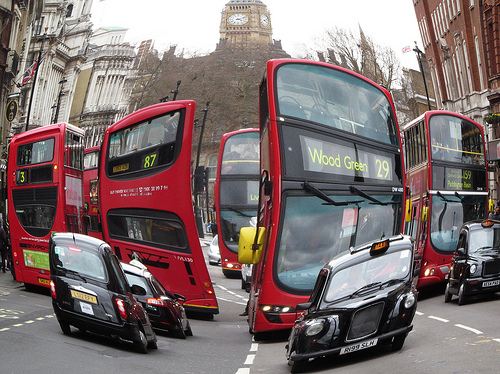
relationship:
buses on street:
[6, 52, 498, 359] [2, 275, 494, 372]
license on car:
[340, 338, 379, 356] [282, 233, 417, 373]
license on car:
[340, 338, 379, 356] [47, 226, 159, 353]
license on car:
[325, 315, 396, 367] [38, 223, 159, 357]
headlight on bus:
[258, 290, 297, 320] [247, 56, 412, 333]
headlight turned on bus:
[258, 290, 297, 320] [247, 56, 412, 333]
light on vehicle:
[307, 320, 321, 335] [286, 233, 416, 371]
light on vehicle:
[404, 296, 415, 309] [286, 233, 416, 371]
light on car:
[106, 289, 130, 324] [49, 216, 158, 354]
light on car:
[40, 268, 61, 304] [49, 216, 158, 354]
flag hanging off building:
[15, 34, 78, 104] [20, 22, 80, 152]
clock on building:
[228, 14, 249, 26] [217, 1, 288, 50]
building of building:
[217, 1, 288, 50] [213, 3, 279, 77]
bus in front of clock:
[237, 58, 411, 342] [228, 14, 249, 26]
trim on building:
[420, 4, 452, 104] [406, 0, 496, 170]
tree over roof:
[131, 42, 408, 147] [254, 49, 397, 101]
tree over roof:
[131, 42, 408, 147] [401, 100, 483, 132]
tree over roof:
[131, 42, 408, 147] [96, 97, 196, 137]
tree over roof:
[131, 42, 408, 147] [8, 123, 87, 147]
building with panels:
[138, 2, 387, 241] [213, 1, 284, 38]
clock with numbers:
[228, 14, 249, 26] [229, 11, 246, 26]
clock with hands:
[228, 14, 249, 26] [258, 11, 268, 28]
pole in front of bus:
[193, 86, 225, 265] [247, 56, 412, 333]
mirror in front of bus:
[237, 225, 265, 262] [247, 56, 412, 333]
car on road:
[282, 233, 417, 373] [1, 244, 499, 371]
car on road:
[282, 233, 417, 373] [4, 268, 476, 363]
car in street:
[284, 232, 419, 373] [1, 243, 481, 364]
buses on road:
[6, 56, 498, 374] [0, 273, 500, 374]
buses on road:
[6, 52, 498, 359] [1, 244, 499, 371]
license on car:
[480, 277, 499, 287] [442, 214, 498, 306]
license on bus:
[37, 273, 53, 285] [7, 120, 95, 285]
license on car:
[67, 286, 98, 303] [47, 226, 159, 353]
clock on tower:
[224, 9, 249, 28] [223, 0, 275, 40]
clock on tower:
[258, 9, 270, 31] [223, 0, 275, 40]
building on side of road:
[316, 1, 500, 213] [6, 256, 477, 367]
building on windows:
[406, 1, 498, 97] [448, 30, 481, 100]